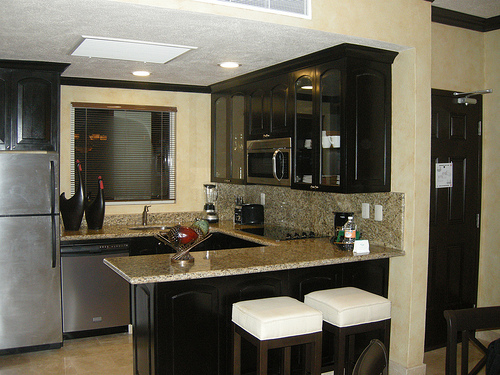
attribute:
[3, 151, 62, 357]
fridge — stainless steel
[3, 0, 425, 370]
kitchen — tiled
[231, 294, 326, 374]
bar stool — white, black, wooden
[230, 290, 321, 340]
cushion — white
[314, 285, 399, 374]
bar stool — white, black, wooden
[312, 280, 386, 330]
cushion — white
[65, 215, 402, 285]
counter — granite, white, brown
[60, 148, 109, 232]
hens — black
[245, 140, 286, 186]
microwave — stainless steel, black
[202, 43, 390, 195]
cabinets — black, wood, glass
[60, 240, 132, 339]
dishwasher — stainless steel, black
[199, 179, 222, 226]
blender — silver, black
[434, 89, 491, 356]
door — black, dark brown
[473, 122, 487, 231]
door hinge — metal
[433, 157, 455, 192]
sign — white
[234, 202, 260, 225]
toaster — black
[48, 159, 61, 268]
handles — black